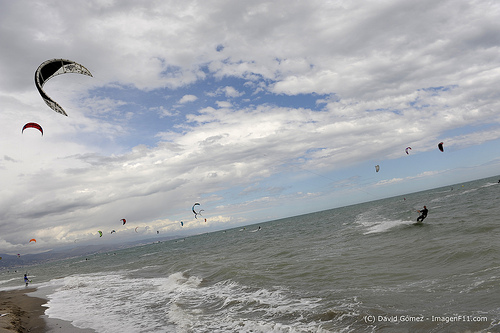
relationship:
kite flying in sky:
[33, 57, 94, 118] [2, 1, 483, 251]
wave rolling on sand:
[39, 286, 140, 331] [2, 286, 102, 331]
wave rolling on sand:
[0, 266, 499, 332] [2, 286, 102, 331]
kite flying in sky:
[20, 121, 45, 137] [2, 1, 483, 251]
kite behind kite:
[20, 121, 45, 137] [17, 44, 99, 117]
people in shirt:
[22, 273, 31, 288] [23, 273, 27, 279]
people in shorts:
[22, 273, 31, 288] [23, 280, 28, 283]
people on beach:
[22, 273, 31, 288] [2, 270, 106, 332]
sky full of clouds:
[0, 0, 499, 257] [0, 0, 499, 255]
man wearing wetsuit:
[413, 204, 429, 224] [417, 204, 432, 223]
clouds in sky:
[0, 0, 499, 255] [4, 0, 495, 270]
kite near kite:
[20, 121, 45, 137] [25, 231, 44, 246]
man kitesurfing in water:
[413, 204, 429, 224] [0, 177, 498, 330]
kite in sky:
[18, 117, 49, 138] [4, 0, 495, 270]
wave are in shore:
[0, 266, 499, 332] [7, 256, 407, 330]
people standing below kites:
[22, 273, 31, 288] [15, 50, 498, 231]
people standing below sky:
[22, 273, 31, 288] [4, 0, 495, 270]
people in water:
[18, 268, 45, 308] [0, 177, 498, 330]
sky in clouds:
[4, 0, 495, 270] [0, 0, 498, 266]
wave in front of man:
[0, 266, 499, 332] [413, 204, 429, 224]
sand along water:
[1, 283, 88, 330] [0, 177, 498, 330]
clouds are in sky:
[0, 0, 498, 266] [4, 0, 495, 270]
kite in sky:
[33, 57, 94, 118] [4, 0, 495, 270]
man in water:
[413, 204, 429, 224] [0, 177, 498, 330]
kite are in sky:
[20, 121, 45, 137] [4, 0, 495, 270]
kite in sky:
[23, 51, 89, 123] [4, 0, 495, 270]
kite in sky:
[20, 121, 45, 137] [4, 0, 495, 270]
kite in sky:
[435, 134, 449, 158] [4, 0, 495, 270]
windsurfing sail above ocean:
[118, 217, 127, 226] [10, 169, 498, 330]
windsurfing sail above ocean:
[13, 112, 48, 144] [10, 169, 498, 330]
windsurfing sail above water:
[118, 217, 127, 226] [0, 175, 499, 332]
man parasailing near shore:
[410, 199, 431, 231] [2, 257, 317, 329]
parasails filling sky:
[14, 54, 463, 253] [4, 0, 495, 270]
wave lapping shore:
[0, 266, 499, 332] [0, 265, 108, 329]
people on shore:
[22, 273, 31, 288] [3, 276, 180, 327]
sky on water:
[4, 0, 495, 270] [0, 175, 499, 332]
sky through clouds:
[4, 0, 495, 270] [0, 0, 498, 266]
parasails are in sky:
[372, 163, 382, 173] [4, 0, 495, 270]